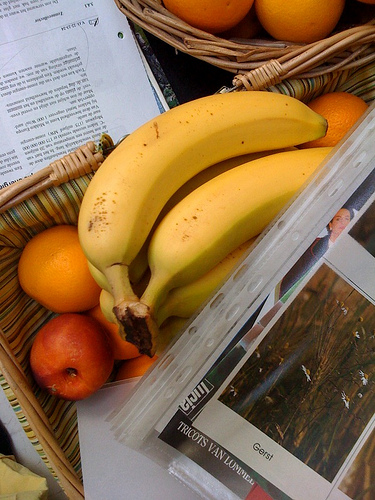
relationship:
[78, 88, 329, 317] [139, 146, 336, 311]
banana next to banana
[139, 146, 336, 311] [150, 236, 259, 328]
banana next to banana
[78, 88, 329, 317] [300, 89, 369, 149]
banana next to orange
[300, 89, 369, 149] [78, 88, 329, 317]
orange next to banana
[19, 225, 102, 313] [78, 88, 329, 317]
apricot next to banana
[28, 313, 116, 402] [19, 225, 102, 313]
apricot next to apricot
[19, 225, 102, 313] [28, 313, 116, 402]
apricot next to apricot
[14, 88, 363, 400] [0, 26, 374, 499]
fruit sitting in basket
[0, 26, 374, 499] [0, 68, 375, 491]
basket has cloth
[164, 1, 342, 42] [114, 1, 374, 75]
fruit are in basket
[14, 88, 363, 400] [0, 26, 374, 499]
fruit sits in basket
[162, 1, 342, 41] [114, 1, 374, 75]
fruit in basket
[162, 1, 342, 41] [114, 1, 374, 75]
fruit sitting in basket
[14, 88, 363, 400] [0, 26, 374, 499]
fruit laying in basket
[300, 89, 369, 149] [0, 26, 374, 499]
orange sitting in basket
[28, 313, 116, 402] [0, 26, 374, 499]
apricot sitting in basket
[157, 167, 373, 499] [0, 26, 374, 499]
paper in basket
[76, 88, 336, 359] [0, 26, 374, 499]
bananas are in basket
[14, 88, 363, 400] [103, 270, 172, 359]
fruit has stem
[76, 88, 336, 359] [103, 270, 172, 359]
bananas have stem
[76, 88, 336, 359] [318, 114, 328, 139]
bananas have end